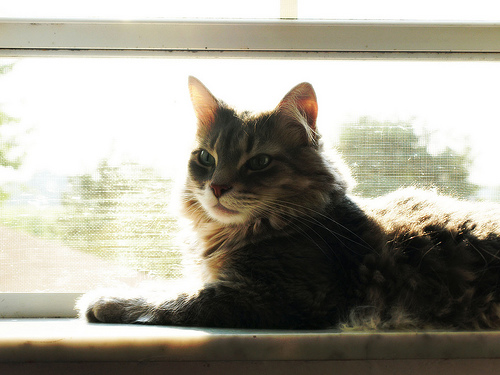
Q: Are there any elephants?
A: No, there are no elephants.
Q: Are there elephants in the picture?
A: No, there are no elephants.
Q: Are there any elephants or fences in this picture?
A: No, there are no elephants or fences.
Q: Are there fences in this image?
A: No, there are no fences.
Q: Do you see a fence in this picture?
A: No, there are no fences.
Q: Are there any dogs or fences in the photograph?
A: No, there are no fences or dogs.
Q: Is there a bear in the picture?
A: No, there are no bears.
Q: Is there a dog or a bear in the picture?
A: No, there are no bears or dogs.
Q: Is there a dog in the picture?
A: No, there are no dogs.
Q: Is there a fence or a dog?
A: No, there are no dogs or fences.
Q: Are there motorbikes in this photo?
A: No, there are no motorbikes.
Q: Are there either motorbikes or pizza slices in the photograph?
A: No, there are no motorbikes or pizza slices.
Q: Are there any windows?
A: Yes, there is a window.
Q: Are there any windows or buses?
A: Yes, there is a window.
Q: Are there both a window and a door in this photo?
A: No, there is a window but no doors.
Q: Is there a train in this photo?
A: No, there are no trains.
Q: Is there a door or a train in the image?
A: No, there are no trains or doors.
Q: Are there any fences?
A: No, there are no fences.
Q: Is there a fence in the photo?
A: No, there are no fences.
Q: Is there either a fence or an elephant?
A: No, there are no fences or elephants.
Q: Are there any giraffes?
A: No, there are no giraffes.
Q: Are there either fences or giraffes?
A: No, there are no giraffes or fences.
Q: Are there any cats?
A: Yes, there is a cat.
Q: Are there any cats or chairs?
A: Yes, there is a cat.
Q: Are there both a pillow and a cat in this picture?
A: No, there is a cat but no pillows.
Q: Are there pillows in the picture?
A: No, there are no pillows.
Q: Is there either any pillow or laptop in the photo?
A: No, there are no pillows or laptops.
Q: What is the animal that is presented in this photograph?
A: The animal is a cat.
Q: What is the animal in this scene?
A: The animal is a cat.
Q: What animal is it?
A: The animal is a cat.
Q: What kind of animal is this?
A: This is a cat.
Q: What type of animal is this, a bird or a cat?
A: This is a cat.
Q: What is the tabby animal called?
A: The animal is a cat.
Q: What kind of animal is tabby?
A: The animal is a cat.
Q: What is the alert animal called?
A: The animal is a cat.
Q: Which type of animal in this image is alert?
A: The animal is a cat.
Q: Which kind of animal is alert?
A: The animal is a cat.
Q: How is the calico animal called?
A: The animal is a cat.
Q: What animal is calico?
A: The animal is a cat.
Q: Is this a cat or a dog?
A: This is a cat.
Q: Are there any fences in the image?
A: No, there are no fences.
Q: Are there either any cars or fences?
A: No, there are no fences or cars.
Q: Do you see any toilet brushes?
A: No, there are no toilet brushes.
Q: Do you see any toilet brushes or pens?
A: No, there are no toilet brushes or pens.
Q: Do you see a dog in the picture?
A: No, there are no dogs.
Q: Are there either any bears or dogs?
A: No, there are no dogs or bears.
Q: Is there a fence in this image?
A: No, there are no fences.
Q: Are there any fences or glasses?
A: No, there are no fences or glasses.